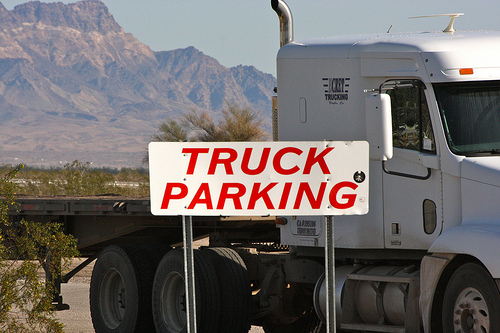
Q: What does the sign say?
A: Truck parking.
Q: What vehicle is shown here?
A: Truck.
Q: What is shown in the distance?
A: Mountains.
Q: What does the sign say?
A: Truck parking.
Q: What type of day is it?
A: Sunny.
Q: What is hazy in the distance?
A: Mountains.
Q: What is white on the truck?
A: Cab.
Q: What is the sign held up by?
A: Poles.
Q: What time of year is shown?
A: Summer.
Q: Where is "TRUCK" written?
A: On a sign.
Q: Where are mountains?
A: In the distance.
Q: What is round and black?
A: Tires.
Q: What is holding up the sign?
A: Two poles.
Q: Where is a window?
A: On the truck.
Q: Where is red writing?
A: On sign.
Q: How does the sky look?
A: Blue and clear.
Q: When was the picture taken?
A: During daytime.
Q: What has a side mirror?
A: The truck.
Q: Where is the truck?
A: On a road.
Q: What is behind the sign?
A: A truck.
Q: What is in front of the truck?
A: A sign.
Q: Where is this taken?
A: A truck stop.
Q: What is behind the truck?
A: Mountains.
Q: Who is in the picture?
A: Nobody is in the picture.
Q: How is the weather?
A: Hot.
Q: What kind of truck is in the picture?
A: A Semi.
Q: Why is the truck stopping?
A: To park.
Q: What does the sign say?
A: Truck parking.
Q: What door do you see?
A: Passenger.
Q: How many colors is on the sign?
A: Two.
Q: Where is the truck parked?
A: Near the sign.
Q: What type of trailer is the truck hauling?
A: Flatbed.